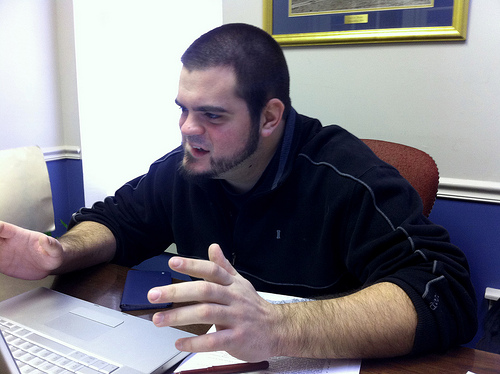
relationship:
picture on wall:
[257, 1, 474, 48] [220, 1, 499, 197]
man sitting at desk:
[17, 20, 471, 372] [77, 255, 301, 331]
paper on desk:
[171, 283, 361, 372] [0, 249, 500, 372]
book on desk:
[119, 265, 172, 311] [3, 261, 483, 371]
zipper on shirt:
[244, 196, 323, 279] [72, 112, 477, 353]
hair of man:
[309, 297, 374, 339] [17, 20, 471, 372]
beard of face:
[175, 121, 276, 191] [153, 14, 304, 189]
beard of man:
[175, 121, 276, 191] [17, 20, 471, 372]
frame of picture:
[275, 24, 458, 39] [263, 2, 467, 51]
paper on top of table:
[181, 287, 367, 372] [1, 225, 497, 369]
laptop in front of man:
[0, 285, 212, 367] [17, 20, 471, 372]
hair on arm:
[274, 299, 416, 346] [157, 173, 478, 362]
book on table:
[97, 246, 205, 324] [0, 261, 499, 371]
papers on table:
[292, 347, 359, 369] [415, 344, 480, 371]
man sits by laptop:
[17, 20, 471, 372] [6, 259, 180, 367]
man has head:
[17, 20, 471, 372] [175, 22, 290, 183]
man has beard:
[17, 20, 471, 372] [176, 115, 261, 182]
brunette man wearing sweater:
[83, 19, 383, 285] [69, 129, 469, 346]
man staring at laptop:
[136, 69, 486, 329] [4, 292, 206, 370]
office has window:
[3, 3, 494, 370] [103, 43, 179, 131]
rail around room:
[43, 142, 498, 209] [2, 0, 494, 368]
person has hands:
[4, 21, 475, 362] [8, 197, 278, 360]